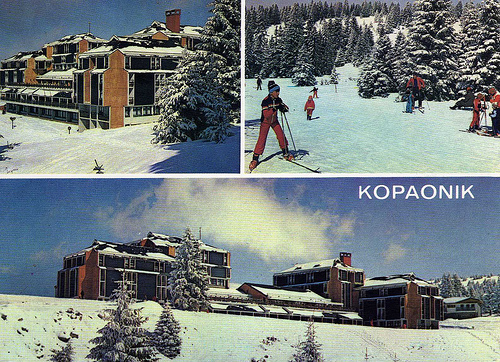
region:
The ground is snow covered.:
[0, 220, 498, 359]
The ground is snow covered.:
[244, 4, 499, 171]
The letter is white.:
[352, 177, 375, 206]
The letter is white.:
[370, 178, 394, 205]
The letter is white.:
[389, 178, 409, 207]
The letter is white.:
[402, 178, 421, 205]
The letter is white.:
[416, 180, 439, 202]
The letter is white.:
[434, 176, 456, 201]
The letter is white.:
[457, 180, 479, 202]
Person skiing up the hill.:
[254, 75, 309, 171]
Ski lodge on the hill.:
[46, 238, 453, 336]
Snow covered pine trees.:
[88, 270, 195, 359]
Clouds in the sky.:
[138, 182, 347, 260]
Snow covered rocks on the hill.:
[9, 307, 94, 339]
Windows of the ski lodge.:
[125, 267, 137, 279]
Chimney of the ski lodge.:
[339, 240, 355, 262]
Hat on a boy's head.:
[264, 80, 282, 92]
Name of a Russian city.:
[350, 182, 486, 210]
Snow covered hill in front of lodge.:
[16, 135, 88, 164]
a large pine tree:
[169, 227, 213, 309]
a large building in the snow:
[57, 224, 444, 330]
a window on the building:
[338, 269, 350, 281]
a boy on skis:
[247, 81, 317, 176]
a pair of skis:
[252, 150, 319, 177]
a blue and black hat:
[265, 80, 279, 92]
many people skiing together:
[252, 73, 497, 168]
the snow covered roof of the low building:
[206, 280, 348, 317]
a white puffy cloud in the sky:
[102, 179, 364, 256]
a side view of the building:
[0, 12, 235, 152]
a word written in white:
[346, 173, 484, 208]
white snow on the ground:
[0, 298, 494, 357]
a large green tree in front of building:
[3, 212, 490, 336]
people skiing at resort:
[233, 64, 495, 179]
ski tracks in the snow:
[50, 143, 164, 165]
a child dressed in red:
[301, 89, 326, 124]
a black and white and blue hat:
[263, 68, 284, 93]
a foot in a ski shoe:
[270, 140, 335, 182]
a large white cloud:
[138, 182, 356, 264]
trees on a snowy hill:
[265, 5, 482, 89]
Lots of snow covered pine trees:
[246, 1, 498, 114]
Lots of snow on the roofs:
[57, 229, 485, 325]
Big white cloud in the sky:
[86, 177, 415, 268]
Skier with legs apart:
[246, 80, 325, 175]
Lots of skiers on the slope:
[245, 72, 499, 174]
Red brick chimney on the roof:
[163, 8, 183, 33]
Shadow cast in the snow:
[144, 119, 241, 173]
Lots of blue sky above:
[2, 179, 499, 299]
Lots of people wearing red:
[251, 74, 499, 154]